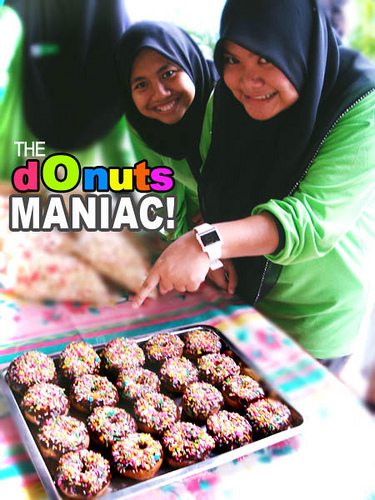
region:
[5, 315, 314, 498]
tray of chocolate frosted and sprinkled doughnuts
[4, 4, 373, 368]
pair of smiling women in burkas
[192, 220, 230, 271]
white electronic watch on woman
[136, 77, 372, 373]
long sleeved green top on woman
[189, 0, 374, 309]
black headdress on foreign woman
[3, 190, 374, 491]
pink and blue table cloth on table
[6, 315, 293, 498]
silver tray for doughnuts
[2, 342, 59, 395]
doughnut heavily iced and sprinkled with rainbow sprinkles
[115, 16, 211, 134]
smiling brown Asian woman with head covered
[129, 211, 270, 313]
woman's hand pointing at doughnuts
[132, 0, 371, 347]
this is a person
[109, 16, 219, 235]
this is a person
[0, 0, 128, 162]
this is a person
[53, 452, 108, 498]
this is a donut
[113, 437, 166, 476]
this is a donut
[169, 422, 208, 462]
this is a donut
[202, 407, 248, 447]
this is a donut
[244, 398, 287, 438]
this is a donut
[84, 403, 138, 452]
this is a donut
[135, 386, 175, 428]
this is a donut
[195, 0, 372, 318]
woman wearing black hijab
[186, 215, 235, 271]
woman wearing white watch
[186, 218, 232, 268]
watch has black face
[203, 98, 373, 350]
woman wearing green top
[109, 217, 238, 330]
woman pointing at donuts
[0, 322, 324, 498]
multiple donuts on tray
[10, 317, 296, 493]
donuts on tray have sprinkles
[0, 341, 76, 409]
donut sprinkles are multicolored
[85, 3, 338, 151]
two women smiling together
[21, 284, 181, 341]
tablecloth is pink and multicolored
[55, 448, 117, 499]
chocolate frosted dount covered with colorful sprinkles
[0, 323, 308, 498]
pan of chocolate frosted donuts covered with sprinkles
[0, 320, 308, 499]
twenty colorful donuts in a pan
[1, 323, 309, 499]
twenty chocolate frosted donuts topped with sprinkles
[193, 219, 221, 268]
white watch on a woman's wrist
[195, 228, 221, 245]
square black screen of a watch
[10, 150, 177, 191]
colorful text print reading Donuts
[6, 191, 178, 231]
white text print reading MANIAC!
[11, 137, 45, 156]
white text print reading THE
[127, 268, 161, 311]
a woman's finger pointing